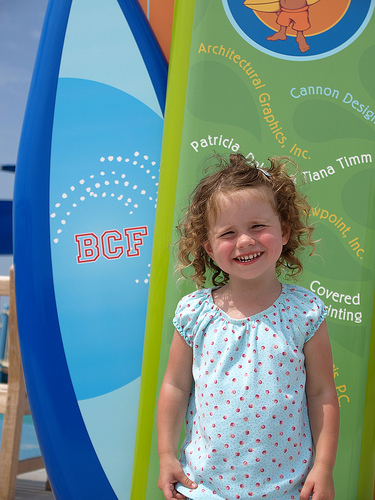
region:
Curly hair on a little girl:
[179, 147, 311, 288]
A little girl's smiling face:
[185, 168, 303, 294]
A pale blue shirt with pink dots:
[171, 284, 342, 496]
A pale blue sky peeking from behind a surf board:
[0, 2, 43, 83]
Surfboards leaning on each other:
[20, 0, 352, 174]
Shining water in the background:
[22, 422, 33, 463]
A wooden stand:
[3, 255, 33, 460]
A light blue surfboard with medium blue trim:
[10, 65, 151, 294]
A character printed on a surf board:
[220, 2, 358, 62]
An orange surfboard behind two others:
[136, 3, 196, 73]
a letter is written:
[73, 227, 99, 268]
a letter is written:
[98, 226, 126, 264]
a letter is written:
[124, 220, 153, 261]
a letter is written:
[189, 137, 199, 152]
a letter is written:
[198, 134, 210, 148]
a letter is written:
[227, 139, 240, 151]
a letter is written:
[254, 88, 274, 104]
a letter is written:
[306, 274, 317, 286]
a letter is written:
[332, 381, 348, 393]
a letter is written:
[343, 288, 361, 310]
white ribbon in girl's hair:
[238, 148, 280, 176]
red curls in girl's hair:
[173, 214, 213, 262]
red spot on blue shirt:
[231, 426, 274, 464]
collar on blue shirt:
[223, 308, 299, 341]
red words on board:
[61, 223, 186, 282]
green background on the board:
[320, 244, 360, 270]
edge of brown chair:
[4, 386, 30, 434]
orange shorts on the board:
[257, 4, 330, 49]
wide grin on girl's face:
[218, 247, 296, 268]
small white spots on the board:
[75, 136, 177, 190]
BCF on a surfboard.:
[64, 223, 152, 268]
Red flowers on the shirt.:
[216, 472, 267, 498]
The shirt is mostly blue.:
[268, 454, 303, 490]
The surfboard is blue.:
[44, 380, 112, 415]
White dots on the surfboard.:
[84, 163, 157, 209]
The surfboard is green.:
[182, 91, 226, 135]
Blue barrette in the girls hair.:
[248, 155, 281, 184]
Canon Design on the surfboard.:
[284, 85, 374, 127]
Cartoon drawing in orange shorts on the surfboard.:
[262, 2, 325, 55]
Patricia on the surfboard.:
[190, 130, 245, 159]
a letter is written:
[315, 284, 327, 295]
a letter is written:
[350, 290, 363, 306]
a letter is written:
[325, 286, 333, 303]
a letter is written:
[350, 309, 362, 322]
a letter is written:
[345, 308, 352, 319]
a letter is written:
[326, 304, 337, 319]